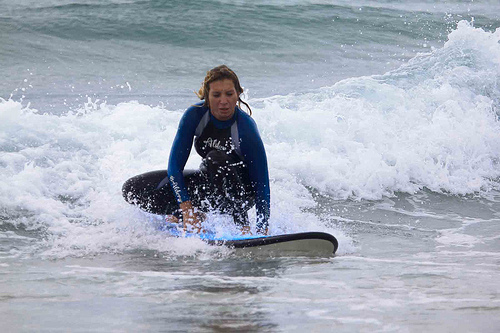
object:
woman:
[121, 63, 271, 237]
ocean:
[1, 1, 499, 333]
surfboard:
[159, 224, 337, 257]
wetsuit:
[121, 103, 270, 233]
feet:
[236, 222, 254, 236]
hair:
[193, 63, 253, 116]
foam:
[1, 17, 500, 255]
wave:
[0, 17, 500, 251]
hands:
[180, 204, 200, 230]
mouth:
[218, 107, 231, 112]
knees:
[122, 182, 144, 199]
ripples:
[0, 2, 499, 72]